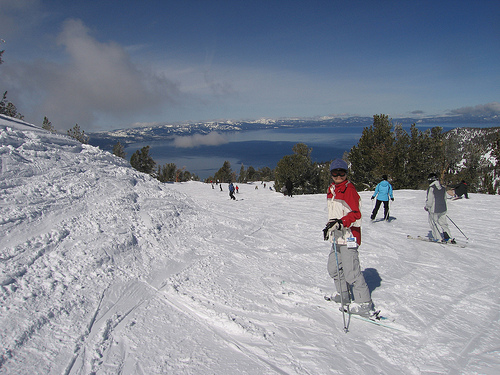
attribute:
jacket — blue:
[371, 184, 392, 203]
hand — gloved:
[316, 217, 352, 252]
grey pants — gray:
[319, 237, 375, 310]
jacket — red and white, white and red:
[325, 178, 362, 245]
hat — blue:
[326, 157, 347, 172]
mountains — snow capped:
[70, 97, 490, 144]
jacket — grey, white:
[423, 183, 444, 215]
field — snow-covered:
[154, 177, 498, 373]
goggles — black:
[328, 164, 349, 183]